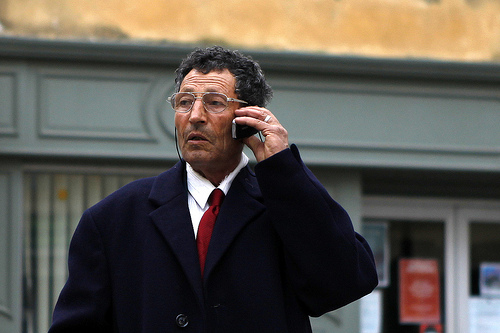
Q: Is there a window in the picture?
A: Yes, there is a window.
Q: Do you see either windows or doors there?
A: Yes, there is a window.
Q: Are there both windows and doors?
A: Yes, there are both a window and a door.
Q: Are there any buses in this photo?
A: No, there are no buses.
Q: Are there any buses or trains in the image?
A: No, there are no buses or trains.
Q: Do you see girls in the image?
A: No, there are no girls.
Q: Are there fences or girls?
A: No, there are no girls or fences.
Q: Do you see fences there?
A: No, there are no fences.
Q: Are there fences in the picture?
A: No, there are no fences.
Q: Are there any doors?
A: Yes, there is a door.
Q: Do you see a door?
A: Yes, there is a door.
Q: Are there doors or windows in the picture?
A: Yes, there is a door.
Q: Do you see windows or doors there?
A: Yes, there is a door.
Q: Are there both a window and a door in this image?
A: Yes, there are both a door and a window.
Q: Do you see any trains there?
A: No, there are no trains.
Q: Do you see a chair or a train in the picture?
A: No, there are no trains or chairs.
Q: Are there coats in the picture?
A: Yes, there is a coat.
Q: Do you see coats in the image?
A: Yes, there is a coat.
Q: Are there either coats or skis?
A: Yes, there is a coat.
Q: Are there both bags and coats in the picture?
A: No, there is a coat but no bags.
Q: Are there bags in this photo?
A: No, there are no bags.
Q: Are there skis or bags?
A: No, there are no bags or skis.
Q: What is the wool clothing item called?
A: The clothing item is a coat.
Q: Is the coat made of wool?
A: Yes, the coat is made of wool.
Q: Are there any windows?
A: Yes, there is a window.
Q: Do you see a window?
A: Yes, there is a window.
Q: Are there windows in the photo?
A: Yes, there is a window.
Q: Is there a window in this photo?
A: Yes, there is a window.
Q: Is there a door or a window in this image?
A: Yes, there is a window.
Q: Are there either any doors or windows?
A: Yes, there is a window.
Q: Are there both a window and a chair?
A: No, there is a window but no chairs.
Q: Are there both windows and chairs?
A: No, there is a window but no chairs.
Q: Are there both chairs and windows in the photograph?
A: No, there is a window but no chairs.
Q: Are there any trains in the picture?
A: No, there are no trains.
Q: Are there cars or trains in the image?
A: No, there are no trains or cars.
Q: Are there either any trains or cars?
A: No, there are no trains or cars.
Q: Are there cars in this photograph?
A: No, there are no cars.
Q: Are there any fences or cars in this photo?
A: No, there are no cars or fences.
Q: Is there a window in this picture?
A: Yes, there is a window.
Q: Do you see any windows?
A: Yes, there is a window.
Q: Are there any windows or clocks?
A: Yes, there is a window.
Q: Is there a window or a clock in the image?
A: Yes, there is a window.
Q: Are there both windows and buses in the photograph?
A: No, there is a window but no buses.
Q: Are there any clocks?
A: No, there are no clocks.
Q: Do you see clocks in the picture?
A: No, there are no clocks.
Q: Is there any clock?
A: No, there are no clocks.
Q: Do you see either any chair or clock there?
A: No, there are no clocks or chairs.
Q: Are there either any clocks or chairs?
A: No, there are no clocks or chairs.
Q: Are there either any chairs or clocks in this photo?
A: No, there are no clocks or chairs.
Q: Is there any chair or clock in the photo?
A: No, there are no clocks or chairs.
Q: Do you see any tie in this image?
A: Yes, there is a tie.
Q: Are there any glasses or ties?
A: Yes, there is a tie.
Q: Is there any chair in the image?
A: No, there are no chairs.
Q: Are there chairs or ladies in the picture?
A: No, there are no chairs or ladies.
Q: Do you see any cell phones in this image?
A: Yes, there is a cell phone.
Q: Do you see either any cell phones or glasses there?
A: Yes, there is a cell phone.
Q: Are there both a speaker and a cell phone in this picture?
A: No, there is a cell phone but no speakers.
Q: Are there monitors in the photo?
A: No, there are no monitors.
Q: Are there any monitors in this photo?
A: No, there are no monitors.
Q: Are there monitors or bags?
A: No, there are no monitors or bags.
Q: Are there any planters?
A: No, there are no planters.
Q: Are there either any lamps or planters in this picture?
A: No, there are no planters or lamps.